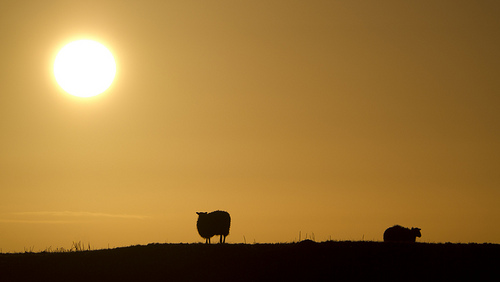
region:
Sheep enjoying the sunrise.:
[196, 209, 231, 243]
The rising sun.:
[49, 35, 119, 101]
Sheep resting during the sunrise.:
[382, 225, 421, 242]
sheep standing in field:
[161, 193, 269, 263]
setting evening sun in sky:
[21, 17, 161, 146]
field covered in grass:
[141, 243, 483, 279]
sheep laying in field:
[356, 203, 456, 253]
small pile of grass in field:
[292, 231, 322, 251]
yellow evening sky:
[201, 22, 498, 191]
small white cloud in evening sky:
[0, 202, 155, 228]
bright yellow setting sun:
[30, 22, 135, 122]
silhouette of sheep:
[176, 191, 264, 257]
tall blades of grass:
[61, 239, 98, 251]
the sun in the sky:
[31, 23, 226, 140]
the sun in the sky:
[30, 18, 147, 130]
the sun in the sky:
[33, 20, 117, 111]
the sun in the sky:
[44, 39, 182, 162]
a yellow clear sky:
[232, 54, 402, 192]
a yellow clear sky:
[236, 40, 397, 165]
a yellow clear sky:
[350, 67, 455, 148]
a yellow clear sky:
[151, 60, 331, 152]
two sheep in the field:
[166, 196, 453, 279]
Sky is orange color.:
[181, 54, 466, 169]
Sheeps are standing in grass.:
[176, 185, 431, 262]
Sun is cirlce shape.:
[43, 31, 138, 112]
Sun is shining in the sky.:
[39, 22, 142, 109]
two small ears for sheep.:
[400, 224, 432, 237]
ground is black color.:
[140, 248, 379, 280]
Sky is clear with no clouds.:
[18, 23, 456, 263]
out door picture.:
[28, 27, 478, 257]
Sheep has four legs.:
[199, 224, 232, 250]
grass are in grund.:
[31, 243, 118, 264]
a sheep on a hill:
[185, 199, 236, 244]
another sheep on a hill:
[379, 213, 424, 251]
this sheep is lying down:
[380, 220, 430, 247]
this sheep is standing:
[193, 209, 233, 242]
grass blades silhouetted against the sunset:
[2, 230, 498, 252]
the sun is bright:
[42, 34, 130, 106]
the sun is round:
[32, 27, 129, 103]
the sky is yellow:
[2, 1, 497, 250]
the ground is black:
[2, 237, 497, 278]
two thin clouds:
[0, 198, 155, 230]